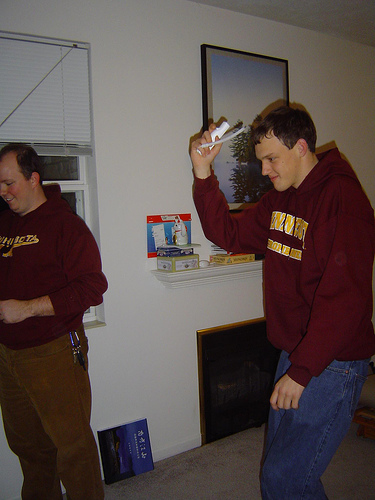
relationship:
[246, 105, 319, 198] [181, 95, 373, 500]
head of person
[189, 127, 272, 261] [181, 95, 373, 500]
arm of person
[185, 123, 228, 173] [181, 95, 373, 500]
hand of person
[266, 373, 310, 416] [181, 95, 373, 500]
hand of person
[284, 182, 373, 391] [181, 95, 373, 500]
arm of person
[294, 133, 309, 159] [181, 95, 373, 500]
ear of person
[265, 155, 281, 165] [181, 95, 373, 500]
eye of person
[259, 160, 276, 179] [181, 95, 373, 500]
nose of person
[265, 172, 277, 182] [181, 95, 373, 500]
mouth of person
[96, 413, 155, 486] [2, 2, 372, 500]
book on wall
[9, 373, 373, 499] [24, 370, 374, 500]
carpet on floor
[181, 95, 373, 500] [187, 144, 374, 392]
person wearing sweater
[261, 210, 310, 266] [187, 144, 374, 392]
logo on sweater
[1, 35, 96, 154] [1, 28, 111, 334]
blinds at window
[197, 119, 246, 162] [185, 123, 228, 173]
remote in hand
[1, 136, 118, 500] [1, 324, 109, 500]
man wearing pants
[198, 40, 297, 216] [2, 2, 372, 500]
picture on wall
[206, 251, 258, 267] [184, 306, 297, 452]
book on fireplace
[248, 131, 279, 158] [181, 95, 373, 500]
forehead of person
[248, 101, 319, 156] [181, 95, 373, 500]
hair of person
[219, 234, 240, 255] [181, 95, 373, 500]
elbow of person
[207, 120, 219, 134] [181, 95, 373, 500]
finger of person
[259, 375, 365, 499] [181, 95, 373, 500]
leg of person